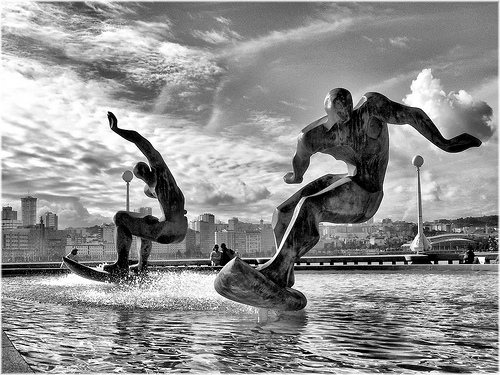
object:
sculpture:
[213, 87, 483, 312]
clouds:
[96, 32, 151, 71]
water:
[33, 312, 88, 351]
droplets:
[156, 287, 180, 305]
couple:
[208, 242, 233, 268]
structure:
[402, 155, 433, 254]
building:
[4, 193, 79, 255]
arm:
[377, 87, 456, 157]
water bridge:
[355, 247, 414, 262]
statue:
[55, 111, 188, 285]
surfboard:
[212, 256, 306, 313]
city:
[0, 194, 499, 261]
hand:
[438, 132, 483, 156]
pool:
[283, 271, 406, 347]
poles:
[118, 183, 134, 212]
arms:
[119, 125, 174, 172]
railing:
[13, 255, 41, 275]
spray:
[139, 274, 163, 296]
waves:
[133, 255, 205, 303]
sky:
[290, 39, 335, 61]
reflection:
[161, 278, 232, 326]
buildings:
[179, 208, 256, 256]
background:
[0, 179, 497, 277]